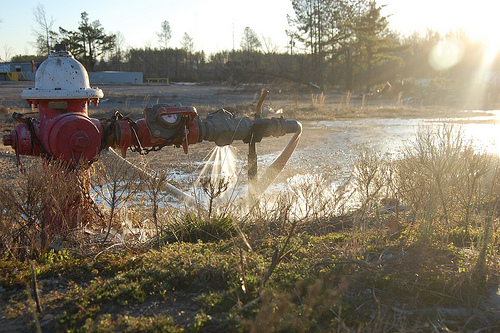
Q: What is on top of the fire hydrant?
A: White cap.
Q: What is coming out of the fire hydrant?
A: Water.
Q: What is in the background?
A: Trees.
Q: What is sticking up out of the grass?
A: Branches.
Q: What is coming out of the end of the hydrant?
A: Hose.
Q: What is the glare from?
A: Sun.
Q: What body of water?
A: River.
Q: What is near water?
A: Hydrant.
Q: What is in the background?
A: Trees.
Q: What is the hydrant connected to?
A: Hose.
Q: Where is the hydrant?
A: Field.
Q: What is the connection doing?
A: Spraying water.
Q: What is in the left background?
A: Building.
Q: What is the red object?
A: Fire hydrant.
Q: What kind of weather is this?
A: Sunny.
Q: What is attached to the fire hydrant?
A: Fire hose.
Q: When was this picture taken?
A: Daytime.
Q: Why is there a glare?
A: From sun.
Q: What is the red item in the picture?
A: Fire hydrant.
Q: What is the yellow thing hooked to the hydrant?
A: Fire hose.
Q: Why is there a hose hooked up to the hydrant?
A: To get water.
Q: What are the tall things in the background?
A: Trees.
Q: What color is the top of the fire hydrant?
A: White.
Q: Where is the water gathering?
A: On the ground.